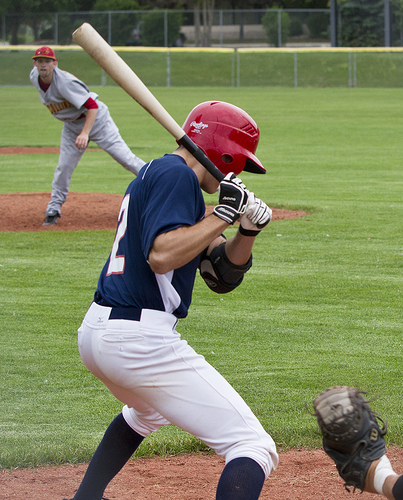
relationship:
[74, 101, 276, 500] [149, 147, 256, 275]
man has skin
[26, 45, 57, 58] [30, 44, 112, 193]
hat on baseball pitcher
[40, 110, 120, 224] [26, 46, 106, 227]
pants on baseball pitcher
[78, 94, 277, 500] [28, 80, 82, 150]
batter looking at pitch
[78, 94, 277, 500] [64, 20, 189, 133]
batter holding bat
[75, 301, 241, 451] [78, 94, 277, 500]
pants on batter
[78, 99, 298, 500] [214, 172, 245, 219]
person has on glove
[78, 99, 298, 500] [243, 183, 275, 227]
person has on glove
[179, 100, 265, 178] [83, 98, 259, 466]
helmet on baseball batter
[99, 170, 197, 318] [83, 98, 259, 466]
jersey on baseball batter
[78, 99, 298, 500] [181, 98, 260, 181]
person wearing helmet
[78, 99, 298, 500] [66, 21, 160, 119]
person holding bat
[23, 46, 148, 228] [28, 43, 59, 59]
person wearing hat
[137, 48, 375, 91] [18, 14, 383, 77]
fence in background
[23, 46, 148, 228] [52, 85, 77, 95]
person wearing grey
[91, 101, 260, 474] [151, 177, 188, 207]
batter wearing blue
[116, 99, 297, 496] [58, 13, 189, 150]
person playing baseball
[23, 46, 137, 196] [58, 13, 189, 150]
person playing baseball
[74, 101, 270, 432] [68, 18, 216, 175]
man holding baseball bat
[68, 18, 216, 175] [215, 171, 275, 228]
baseball bat in hands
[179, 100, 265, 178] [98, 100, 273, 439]
helmet on player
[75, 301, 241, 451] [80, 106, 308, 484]
pants are player's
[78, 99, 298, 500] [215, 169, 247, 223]
person wearing glove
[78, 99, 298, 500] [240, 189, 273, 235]
person wearing glove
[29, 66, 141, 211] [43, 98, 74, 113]
uniform with detail